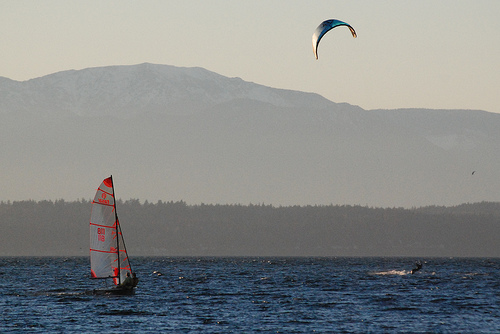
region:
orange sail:
[64, 171, 145, 295]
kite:
[301, 3, 363, 63]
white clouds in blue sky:
[55, 41, 83, 61]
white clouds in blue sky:
[188, 29, 226, 84]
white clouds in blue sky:
[122, 26, 167, 83]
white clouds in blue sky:
[310, 143, 358, 173]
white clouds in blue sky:
[420, 26, 471, 90]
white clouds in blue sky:
[324, 35, 382, 103]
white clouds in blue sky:
[220, 15, 290, 102]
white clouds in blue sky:
[127, 6, 205, 63]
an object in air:
[293, 16, 403, 84]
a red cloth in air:
[81, 169, 155, 314]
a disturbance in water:
[333, 256, 492, 305]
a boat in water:
[41, 167, 191, 330]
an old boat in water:
[36, 147, 185, 332]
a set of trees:
[16, 197, 498, 264]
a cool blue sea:
[22, 248, 489, 330]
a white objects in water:
[145, 260, 215, 293]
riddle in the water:
[179, 283, 369, 333]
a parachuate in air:
[283, 10, 387, 71]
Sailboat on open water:
[85, 172, 142, 294]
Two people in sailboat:
[121, 271, 141, 283]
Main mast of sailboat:
[108, 174, 120, 283]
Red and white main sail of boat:
[85, 175, 130, 282]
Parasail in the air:
[307, 16, 359, 59]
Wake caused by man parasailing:
[368, 266, 407, 280]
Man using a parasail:
[305, 18, 435, 276]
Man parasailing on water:
[407, 260, 430, 275]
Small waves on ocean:
[99, 302, 228, 329]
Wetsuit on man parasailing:
[410, 261, 423, 276]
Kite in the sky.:
[298, 15, 400, 86]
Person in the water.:
[344, 209, 464, 287]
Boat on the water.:
[73, 174, 207, 331]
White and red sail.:
[61, 149, 185, 331]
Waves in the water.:
[165, 230, 304, 324]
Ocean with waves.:
[154, 230, 341, 330]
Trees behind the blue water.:
[207, 139, 362, 246]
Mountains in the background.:
[128, 49, 453, 262]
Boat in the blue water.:
[68, 157, 170, 309]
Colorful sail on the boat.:
[71, 161, 166, 316]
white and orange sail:
[77, 176, 144, 270]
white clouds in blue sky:
[21, 22, 71, 57]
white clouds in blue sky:
[207, 73, 252, 118]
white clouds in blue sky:
[372, 25, 413, 90]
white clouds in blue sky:
[275, 53, 356, 121]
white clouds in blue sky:
[158, 29, 272, 81]